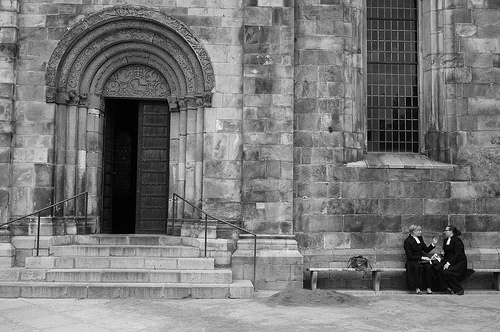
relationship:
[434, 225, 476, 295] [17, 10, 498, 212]
lady sitting on side of building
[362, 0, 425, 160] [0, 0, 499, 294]
window on building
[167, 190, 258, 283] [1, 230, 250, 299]
metal rail along stairs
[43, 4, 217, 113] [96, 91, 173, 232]
arch way over door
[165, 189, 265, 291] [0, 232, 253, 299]
railing on stairs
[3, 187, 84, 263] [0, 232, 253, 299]
railing on stairs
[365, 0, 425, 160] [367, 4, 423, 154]
bars across window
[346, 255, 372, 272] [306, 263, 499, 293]
bag on bench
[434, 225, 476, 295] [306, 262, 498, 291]
lady sitting on bench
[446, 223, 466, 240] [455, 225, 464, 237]
hair in ponytail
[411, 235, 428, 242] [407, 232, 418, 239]
collar around neck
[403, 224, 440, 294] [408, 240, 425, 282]
lady wearing dress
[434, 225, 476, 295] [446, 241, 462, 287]
lady wearing dress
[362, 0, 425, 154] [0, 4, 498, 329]
window on building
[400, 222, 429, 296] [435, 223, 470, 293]
lady talking to lady